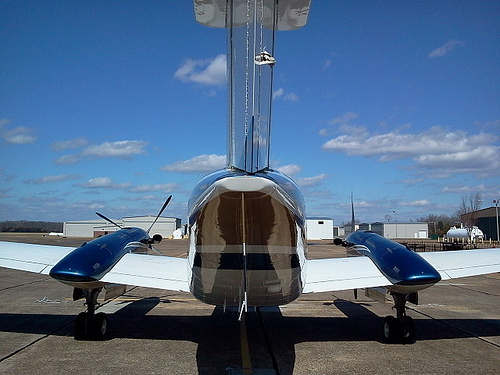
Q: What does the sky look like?
A: Blue and white clouds.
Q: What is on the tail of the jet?
A: Silver and blue.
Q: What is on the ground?
A: Shadow.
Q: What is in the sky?
A: Clouds.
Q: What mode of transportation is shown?
A: Plane.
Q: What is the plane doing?
A: Parked.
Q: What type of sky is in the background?
A: Blue sky.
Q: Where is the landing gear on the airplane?
A: Under the wings.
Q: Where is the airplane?
A: On the tarmac.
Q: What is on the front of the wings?
A: Propellers.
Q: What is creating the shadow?
A: The airplane.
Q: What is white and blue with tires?
A: The airplane.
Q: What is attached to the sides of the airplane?
A: The wings.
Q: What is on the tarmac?
A: The airplane.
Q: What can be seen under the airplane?
A: The shadow.